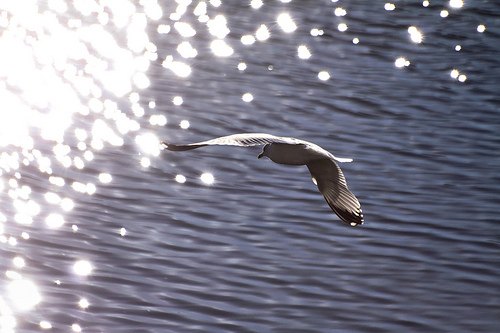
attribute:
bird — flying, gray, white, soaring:
[158, 121, 372, 233]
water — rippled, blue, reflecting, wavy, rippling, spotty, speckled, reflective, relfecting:
[4, 7, 499, 330]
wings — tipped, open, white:
[166, 131, 375, 230]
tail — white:
[308, 144, 355, 167]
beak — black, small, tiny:
[256, 148, 267, 158]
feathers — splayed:
[318, 159, 375, 230]